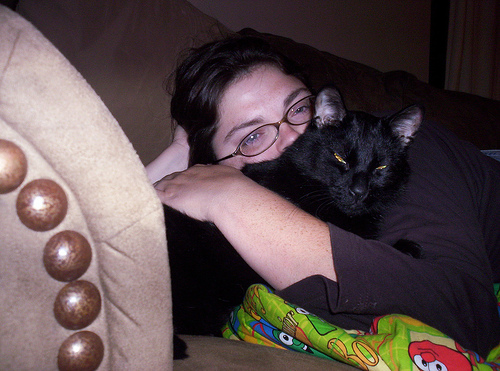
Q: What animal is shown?
A: Cat.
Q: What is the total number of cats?
A: 1.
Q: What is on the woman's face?
A: Glasses.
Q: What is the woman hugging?
A: Cat.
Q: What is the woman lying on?
A: Couch.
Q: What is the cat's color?
A: Black.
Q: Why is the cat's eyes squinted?
A: It is falling asleep.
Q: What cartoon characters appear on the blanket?
A: Veggie Tales.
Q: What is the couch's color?
A: Gray.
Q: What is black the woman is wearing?
A: Shirt.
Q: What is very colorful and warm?
A: The blanket.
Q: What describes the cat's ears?
A: Pointed.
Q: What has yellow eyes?
A: The cat.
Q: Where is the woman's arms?
A: Around the cat.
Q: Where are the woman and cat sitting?
A: On the couch.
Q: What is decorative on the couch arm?
A: Buttons.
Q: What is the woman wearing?
A: Glasses.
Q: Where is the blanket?
A: Under the woman.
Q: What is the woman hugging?
A: A cat.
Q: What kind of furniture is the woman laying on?
A: A sofa.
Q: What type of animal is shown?
A: Cat.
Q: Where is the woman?
A: Couch.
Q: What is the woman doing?
A: Hugging cat.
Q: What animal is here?
A: Cat.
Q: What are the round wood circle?
A: Couch decoration.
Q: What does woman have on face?
A: Glasses.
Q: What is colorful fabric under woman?
A: Blanket.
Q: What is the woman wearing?
A: Brown shirt.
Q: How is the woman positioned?
A: Lying down with head propped up.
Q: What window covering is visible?
A: Tan curtain.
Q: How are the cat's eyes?
A: Half open.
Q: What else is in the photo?
A: Cat.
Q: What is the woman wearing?
A: Glasses.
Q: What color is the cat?
A: Black.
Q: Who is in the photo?
A: A woman.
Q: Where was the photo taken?
A: On a couch.